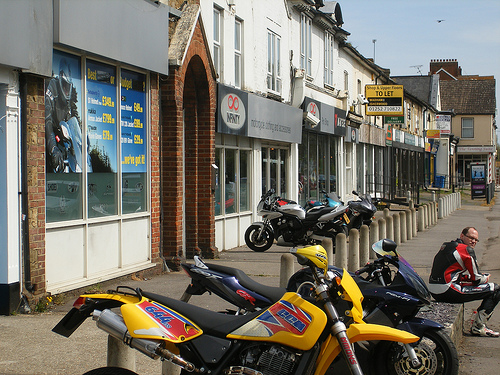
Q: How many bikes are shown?
A: Five.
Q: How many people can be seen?
A: One.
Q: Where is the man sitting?
A: A block.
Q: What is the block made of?
A: Stone.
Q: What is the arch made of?
A: Bricks.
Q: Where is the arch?
A: On the building.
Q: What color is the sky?
A: Blue.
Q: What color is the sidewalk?
A: Gray.